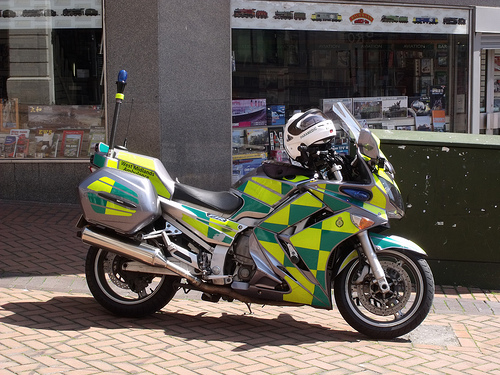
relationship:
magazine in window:
[232, 101, 273, 131] [232, 22, 477, 171]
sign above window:
[350, 9, 375, 29] [232, 22, 477, 171]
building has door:
[2, 6, 487, 285] [474, 6, 500, 143]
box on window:
[430, 108, 446, 131] [232, 22, 477, 171]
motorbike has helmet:
[80, 66, 440, 340] [280, 110, 338, 161]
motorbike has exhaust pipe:
[80, 66, 440, 340] [78, 225, 205, 291]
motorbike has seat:
[80, 66, 440, 340] [174, 181, 247, 218]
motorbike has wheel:
[80, 66, 440, 340] [333, 240, 437, 341]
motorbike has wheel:
[80, 66, 440, 340] [84, 231, 181, 311]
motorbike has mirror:
[80, 66, 440, 340] [356, 133, 386, 169]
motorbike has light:
[80, 66, 440, 340] [351, 212, 379, 233]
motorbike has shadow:
[80, 66, 440, 340] [5, 295, 390, 354]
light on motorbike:
[86, 139, 113, 169] [80, 66, 440, 340]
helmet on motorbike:
[280, 110, 338, 161] [80, 66, 440, 340]